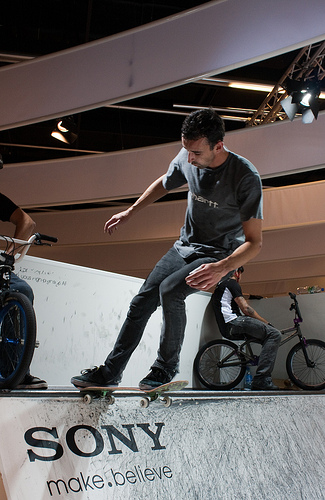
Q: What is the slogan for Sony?
A: Make. Believe.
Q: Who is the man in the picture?
A: A skateboarder.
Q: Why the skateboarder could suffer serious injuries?
A: No protective gear.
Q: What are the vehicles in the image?
A: Bicycles.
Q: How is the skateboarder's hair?
A: Short.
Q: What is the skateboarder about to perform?
A: A trick.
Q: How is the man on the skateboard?
A: Standing on a ledge.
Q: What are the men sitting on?
A: Bicycles.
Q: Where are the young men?
A: Indoor skatepark.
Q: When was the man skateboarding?
A: Saturday afternoon.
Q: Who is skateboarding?
A: A man in a blue t-shirt.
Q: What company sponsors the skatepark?
A: Sony.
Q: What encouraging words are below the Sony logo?
A: Make and believe.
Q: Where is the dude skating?
A: On top of sony logo.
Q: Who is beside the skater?
A: Two bikers.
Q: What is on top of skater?
A: Lighting.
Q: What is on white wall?
A: Kick-grab marks.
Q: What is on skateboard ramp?
A: Sign.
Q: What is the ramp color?
A: Black and tan.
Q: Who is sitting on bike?
A: Young man.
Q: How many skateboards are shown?
A: One.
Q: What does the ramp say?
A: Sony.